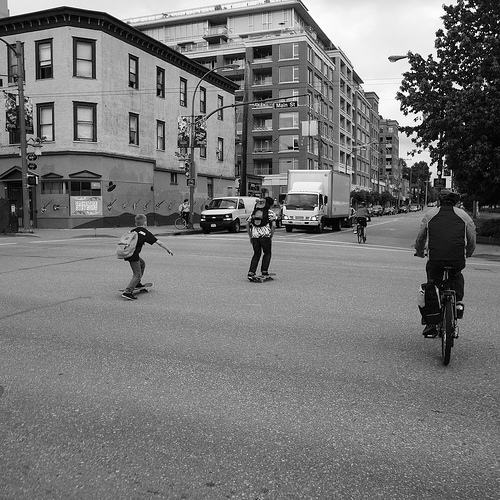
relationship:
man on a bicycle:
[413, 186, 480, 363] [413, 244, 464, 364]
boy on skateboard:
[114, 210, 176, 302] [114, 278, 155, 295]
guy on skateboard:
[244, 194, 278, 285] [241, 267, 281, 285]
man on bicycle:
[351, 207, 368, 221] [352, 217, 369, 242]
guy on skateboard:
[244, 194, 278, 285] [115, 264, 158, 308]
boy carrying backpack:
[116, 210, 178, 302] [117, 227, 141, 259]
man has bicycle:
[411, 188, 478, 339] [413, 245, 470, 359]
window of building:
[73, 100, 95, 141] [3, 11, 255, 223]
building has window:
[3, 11, 255, 223] [127, 55, 137, 89]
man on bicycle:
[411, 188, 478, 339] [438, 278, 456, 369]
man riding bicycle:
[351, 197, 371, 245] [344, 195, 373, 245]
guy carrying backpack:
[244, 182, 285, 282] [245, 188, 292, 238]